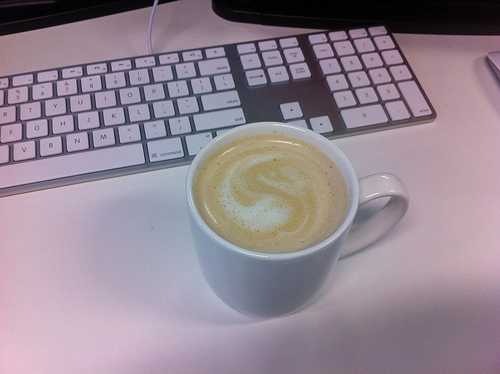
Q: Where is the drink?
A: In front of the keyboard.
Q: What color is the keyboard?
A: White and silver.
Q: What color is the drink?
A: Brown and white.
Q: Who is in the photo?
A: No one.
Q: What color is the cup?
A: White.